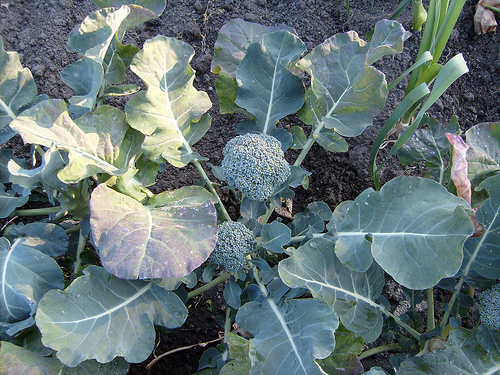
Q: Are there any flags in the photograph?
A: No, there are no flags.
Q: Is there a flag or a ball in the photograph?
A: No, there are no flags or balls.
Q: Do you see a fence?
A: No, there are no fences.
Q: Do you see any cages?
A: No, there are no cages.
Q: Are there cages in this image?
A: No, there are no cages.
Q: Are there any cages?
A: No, there are no cages.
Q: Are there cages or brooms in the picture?
A: No, there are no cages or brooms.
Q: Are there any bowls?
A: No, there are no bowls.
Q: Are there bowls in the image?
A: No, there are no bowls.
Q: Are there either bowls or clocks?
A: No, there are no bowls or clocks.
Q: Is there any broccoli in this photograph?
A: Yes, there is broccoli.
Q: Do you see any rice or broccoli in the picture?
A: Yes, there is broccoli.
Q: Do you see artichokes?
A: No, there are no artichokes.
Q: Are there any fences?
A: No, there are no fences.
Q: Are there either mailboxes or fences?
A: No, there are no fences or mailboxes.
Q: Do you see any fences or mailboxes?
A: No, there are no fences or mailboxes.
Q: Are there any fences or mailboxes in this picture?
A: No, there are no fences or mailboxes.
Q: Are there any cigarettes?
A: No, there are no cigarettes.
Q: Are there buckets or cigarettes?
A: No, there are no cigarettes or buckets.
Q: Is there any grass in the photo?
A: Yes, there is grass.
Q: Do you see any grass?
A: Yes, there is grass.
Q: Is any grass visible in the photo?
A: Yes, there is grass.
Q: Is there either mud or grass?
A: Yes, there is grass.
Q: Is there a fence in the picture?
A: No, there are no fences.